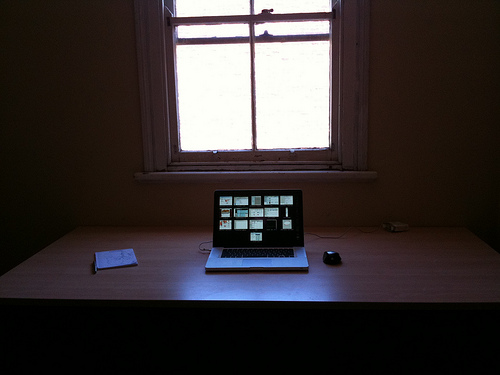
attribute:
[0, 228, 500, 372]
desk — reflective, wooden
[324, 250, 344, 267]
mouse — black, wireless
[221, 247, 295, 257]
keyboard — black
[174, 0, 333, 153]
window — glass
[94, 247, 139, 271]
paper — white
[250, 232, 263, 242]
picture — small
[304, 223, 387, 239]
cable — black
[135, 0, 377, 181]
sill — white